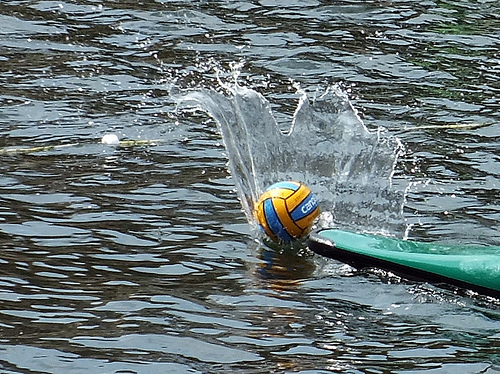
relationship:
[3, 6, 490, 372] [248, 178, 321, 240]
water on ball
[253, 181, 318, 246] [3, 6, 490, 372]
ball in water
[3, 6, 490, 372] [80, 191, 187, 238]
water with some ripples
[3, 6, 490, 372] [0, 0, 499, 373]
water with some ripples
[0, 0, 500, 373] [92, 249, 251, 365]
water with some ripples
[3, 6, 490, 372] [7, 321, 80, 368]
water has ripples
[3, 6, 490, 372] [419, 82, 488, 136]
water has ripples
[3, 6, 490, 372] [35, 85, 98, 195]
water has ripples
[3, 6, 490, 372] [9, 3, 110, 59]
water has ripples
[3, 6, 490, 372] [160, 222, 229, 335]
water has ripples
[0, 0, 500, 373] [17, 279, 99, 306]
water has ripples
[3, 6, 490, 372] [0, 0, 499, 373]
water has ripples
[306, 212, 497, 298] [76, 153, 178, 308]
object in water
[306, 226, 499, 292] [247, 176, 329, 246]
object near ball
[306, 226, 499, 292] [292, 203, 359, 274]
object has tip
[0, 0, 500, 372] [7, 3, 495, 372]
ripples on murky water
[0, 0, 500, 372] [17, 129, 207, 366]
ripples on murky water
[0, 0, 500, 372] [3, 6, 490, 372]
ripples on water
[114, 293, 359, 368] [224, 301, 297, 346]
ripples on murky water